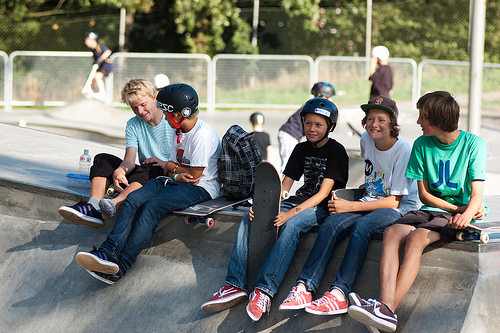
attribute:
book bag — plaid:
[219, 125, 260, 196]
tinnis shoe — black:
[76, 251, 119, 272]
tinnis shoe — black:
[58, 198, 105, 228]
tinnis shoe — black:
[84, 270, 123, 284]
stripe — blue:
[94, 250, 102, 260]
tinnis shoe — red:
[201, 285, 251, 316]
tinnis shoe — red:
[247, 286, 270, 321]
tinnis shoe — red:
[279, 287, 313, 310]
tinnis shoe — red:
[305, 292, 348, 315]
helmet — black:
[300, 99, 338, 146]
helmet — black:
[158, 83, 199, 119]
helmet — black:
[311, 80, 335, 100]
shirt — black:
[282, 138, 348, 214]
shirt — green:
[408, 129, 488, 218]